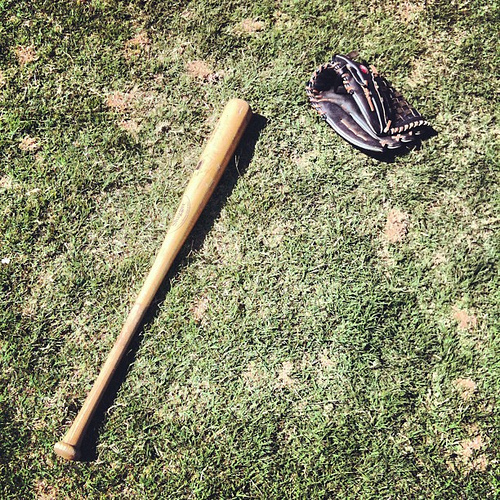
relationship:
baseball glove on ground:
[308, 57, 433, 159] [4, 1, 500, 499]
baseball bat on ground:
[54, 98, 253, 461] [4, 1, 500, 499]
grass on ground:
[264, 190, 402, 324] [4, 1, 500, 499]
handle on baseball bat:
[43, 319, 154, 465] [54, 98, 253, 461]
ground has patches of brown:
[4, 1, 500, 499] [104, 82, 157, 133]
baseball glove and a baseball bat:
[308, 57, 433, 159] [54, 98, 253, 461]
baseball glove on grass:
[308, 57, 433, 159] [264, 190, 402, 324]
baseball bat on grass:
[54, 98, 253, 461] [264, 190, 402, 324]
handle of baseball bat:
[43, 319, 154, 465] [54, 98, 253, 461]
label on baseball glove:
[360, 62, 371, 77] [308, 57, 433, 159]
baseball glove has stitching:
[308, 57, 433, 159] [389, 121, 430, 133]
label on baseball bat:
[164, 197, 198, 232] [54, 98, 253, 461]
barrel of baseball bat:
[163, 91, 248, 260] [54, 98, 253, 461]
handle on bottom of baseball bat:
[43, 319, 154, 465] [54, 98, 253, 461]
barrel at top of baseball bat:
[163, 91, 248, 260] [54, 98, 253, 461]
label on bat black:
[164, 197, 198, 232] [177, 209, 182, 210]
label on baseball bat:
[360, 62, 371, 77] [54, 98, 253, 461]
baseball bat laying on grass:
[54, 98, 253, 461] [264, 190, 402, 324]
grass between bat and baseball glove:
[264, 190, 402, 324] [308, 57, 433, 159]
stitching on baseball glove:
[389, 121, 430, 133] [308, 57, 433, 159]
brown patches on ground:
[104, 82, 157, 133] [4, 1, 500, 499]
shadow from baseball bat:
[147, 108, 268, 313] [54, 98, 253, 461]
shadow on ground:
[147, 108, 268, 313] [4, 1, 500, 499]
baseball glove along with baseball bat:
[308, 57, 433, 159] [54, 98, 253, 461]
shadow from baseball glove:
[362, 127, 443, 164] [308, 57, 433, 159]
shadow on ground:
[362, 127, 443, 164] [4, 1, 500, 499]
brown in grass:
[104, 82, 157, 133] [264, 190, 402, 324]